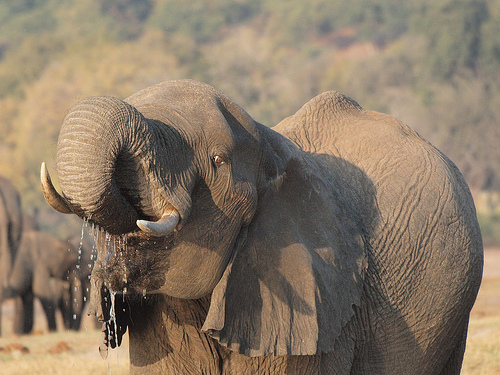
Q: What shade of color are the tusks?
A: White.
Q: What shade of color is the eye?
A: Brown.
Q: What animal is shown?
A: Elephant.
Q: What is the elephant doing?
A: Drinking water.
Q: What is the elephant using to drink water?
A: Trunk.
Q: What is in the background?
A: Trees.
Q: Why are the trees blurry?
A: Focus on the elephant.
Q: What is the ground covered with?
A: Grass.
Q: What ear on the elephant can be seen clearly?
A: Left.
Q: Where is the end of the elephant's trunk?
A: Mouth.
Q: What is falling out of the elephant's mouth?
A: Water.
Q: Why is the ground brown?
A: Dry.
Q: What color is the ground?
A: Brown.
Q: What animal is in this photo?
A: Elephant.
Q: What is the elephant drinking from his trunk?
A: Water.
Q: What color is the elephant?
A: Grey.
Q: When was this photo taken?
A: Daytime.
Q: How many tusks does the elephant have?
A: Two.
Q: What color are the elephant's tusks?
A: White.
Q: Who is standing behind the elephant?
A: No one.